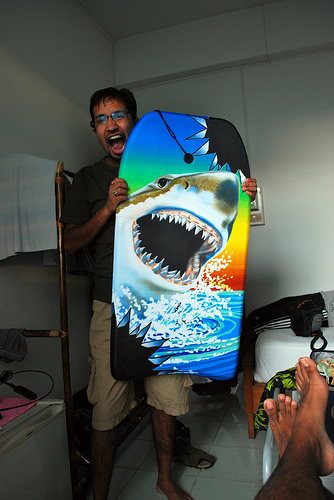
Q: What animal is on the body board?
A: A shark.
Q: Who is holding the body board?
A: A man.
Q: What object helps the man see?
A: The glasses.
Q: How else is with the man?
A: Another person.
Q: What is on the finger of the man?
A: A ring.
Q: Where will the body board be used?
A: In the water.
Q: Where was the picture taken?
A: In a room.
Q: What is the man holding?
A: A board.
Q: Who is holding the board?
A: A man.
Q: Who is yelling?
A: A man.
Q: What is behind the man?
A: A bed.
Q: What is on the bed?
A: A camera.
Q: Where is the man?
A: In a room.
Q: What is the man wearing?
A: A shirt.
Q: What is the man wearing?
A: Shorts.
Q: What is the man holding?
A: A board.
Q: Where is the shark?
A: On the surfboard.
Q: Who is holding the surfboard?
A: The man.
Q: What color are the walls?
A: White.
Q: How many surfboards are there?
A: One.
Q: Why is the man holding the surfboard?
A: He is posing for a picture.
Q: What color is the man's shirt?
A: Black.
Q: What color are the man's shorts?
A: Khaki.